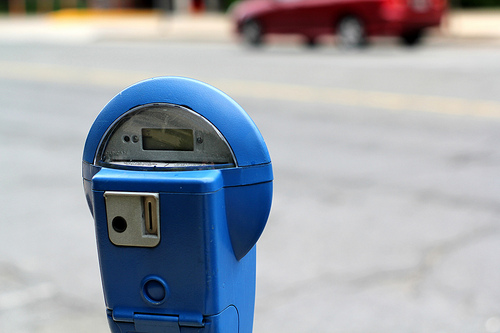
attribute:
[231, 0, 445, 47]
car — red, parked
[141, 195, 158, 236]
coin slot — silver, metal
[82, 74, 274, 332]
parking meter — blue, bright royal blue, empty, vintage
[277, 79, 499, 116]
road line — yellow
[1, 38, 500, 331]
street — grey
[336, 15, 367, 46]
tire — black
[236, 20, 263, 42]
tire — black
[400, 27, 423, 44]
tire — black